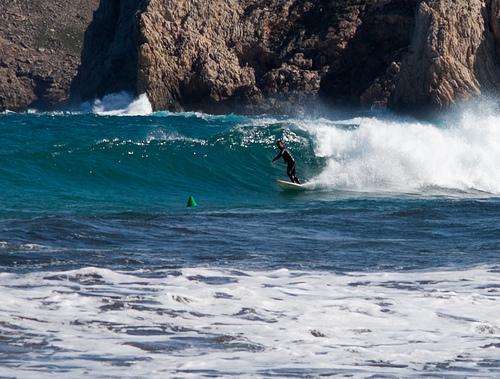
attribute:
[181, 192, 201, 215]
cone — floating, pointed, green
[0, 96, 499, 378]
water — foamy, calm, blue, bright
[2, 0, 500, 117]
stone — rough, tall, natural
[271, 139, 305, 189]
surfer — headed, upright, leaning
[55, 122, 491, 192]
wave — cresting, crested, churning, rough, small, crashing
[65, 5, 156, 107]
crevasse — shadowy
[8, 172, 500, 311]
surface — colors, water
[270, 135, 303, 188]
man — surfig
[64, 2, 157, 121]
shadow — cast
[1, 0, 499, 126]
formation — portruding, rock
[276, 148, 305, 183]
wetsuit — black